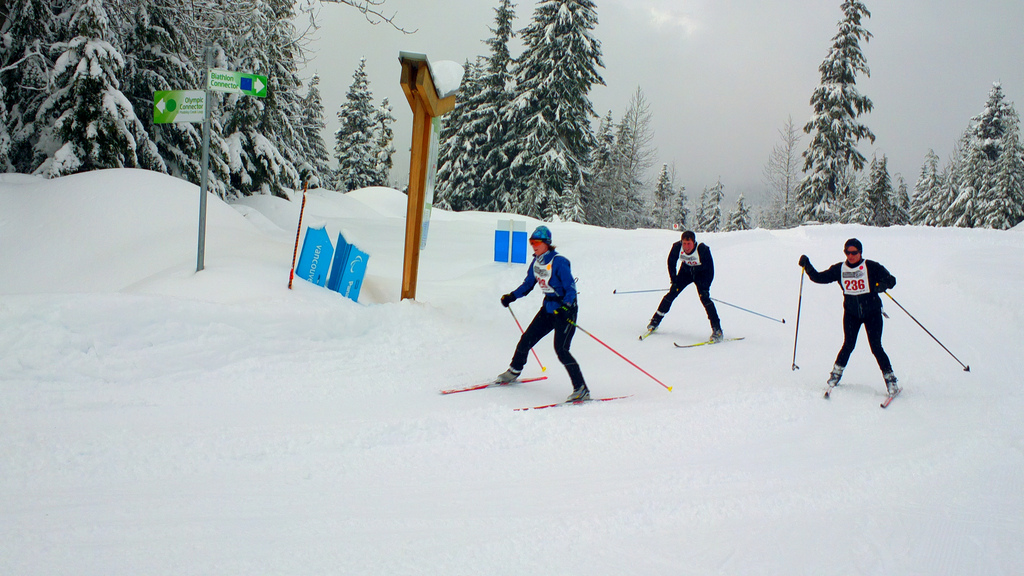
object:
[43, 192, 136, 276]
snow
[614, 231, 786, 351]
person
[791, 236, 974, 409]
person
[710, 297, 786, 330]
ski pole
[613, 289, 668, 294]
ski pole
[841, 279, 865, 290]
number